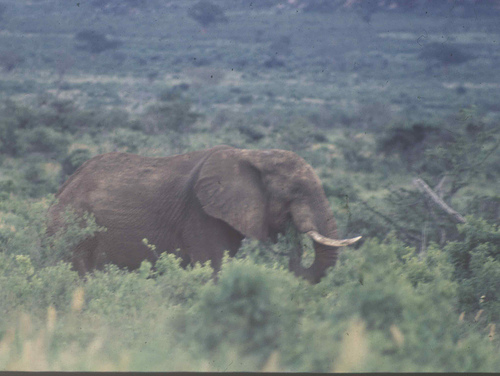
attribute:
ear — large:
[190, 147, 263, 243]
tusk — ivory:
[306, 227, 367, 251]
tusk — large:
[303, 227, 361, 246]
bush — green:
[161, 272, 326, 374]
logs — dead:
[368, 171, 480, 250]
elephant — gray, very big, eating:
[30, 136, 366, 287]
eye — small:
[278, 194, 292, 208]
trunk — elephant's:
[291, 196, 359, 291]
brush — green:
[17, 9, 474, 115]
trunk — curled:
[284, 219, 341, 283]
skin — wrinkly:
[103, 188, 196, 246]